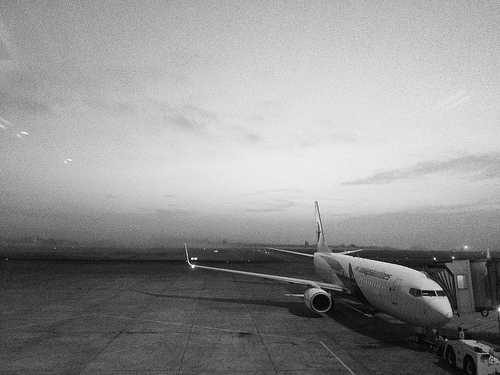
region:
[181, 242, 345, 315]
the right wing on a plane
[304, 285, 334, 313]
the right engine on a plane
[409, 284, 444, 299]
the front windshield on a plane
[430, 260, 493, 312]
the exit of a plane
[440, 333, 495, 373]
a track on the tarmac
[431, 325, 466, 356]
people on the tarmac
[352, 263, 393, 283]
words on the side of a plane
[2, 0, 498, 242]
light in daytime sky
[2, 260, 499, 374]
surface of airport tarmac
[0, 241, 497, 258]
strip of land on horizon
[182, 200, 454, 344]
plane parked on tarmac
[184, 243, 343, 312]
jet engine under plane wing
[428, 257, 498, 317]
boarding ramp attached to plane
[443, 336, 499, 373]
luggage vehicle on tarmc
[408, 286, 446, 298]
windows of plane cockpit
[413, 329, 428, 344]
wheels of landing gear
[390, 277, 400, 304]
door on side of plane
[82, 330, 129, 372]
a crack in the road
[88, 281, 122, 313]
a crack in the road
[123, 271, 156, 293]
a crack in the road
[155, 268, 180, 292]
a crack in the road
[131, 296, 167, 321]
a crack in the road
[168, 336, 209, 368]
a crack in the road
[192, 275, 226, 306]
a crack in the road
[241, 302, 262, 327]
a crack in the road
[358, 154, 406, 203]
Large cloud in the sky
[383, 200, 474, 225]
Large cloud in the sky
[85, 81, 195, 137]
Large cloud in the sky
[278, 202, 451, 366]
Large white airplane in the runway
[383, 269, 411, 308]
Large door on an airplane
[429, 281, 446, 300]
Small window on an airplane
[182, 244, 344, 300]
The left large sidewing of the plane.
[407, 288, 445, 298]
The windows of the cockpit.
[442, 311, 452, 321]
The nose of the plane.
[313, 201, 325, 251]
The tail of the plane.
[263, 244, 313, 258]
The left tail wing.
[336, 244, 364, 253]
The right tail wing.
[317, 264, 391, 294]
The passenger windows of the plane.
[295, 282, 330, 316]
The engine under the left sidewing.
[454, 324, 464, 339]
The person standing in front of the plane.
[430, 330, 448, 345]
The two people sitting in front of the plane.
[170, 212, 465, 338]
airplane on the tarmac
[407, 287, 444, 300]
windows to the cockpit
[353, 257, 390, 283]
lettering on the airplance